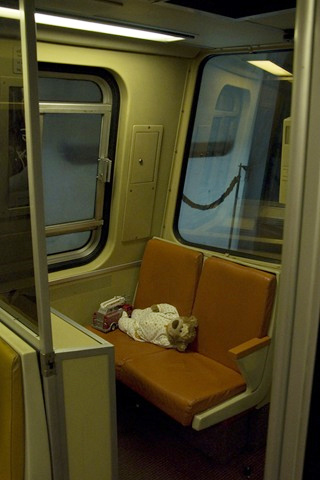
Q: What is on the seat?
A: A teddy bear.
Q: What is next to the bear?
A: A fire engine.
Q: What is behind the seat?
A: A window.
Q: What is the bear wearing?
A: Pajamas.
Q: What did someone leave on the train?
A: Toys.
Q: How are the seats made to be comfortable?
A: With cushions.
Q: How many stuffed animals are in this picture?
A: One.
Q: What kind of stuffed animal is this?
A: Teddy Bear.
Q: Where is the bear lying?
A: On the seat.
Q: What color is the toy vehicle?
A: Red.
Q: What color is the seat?
A: Brown.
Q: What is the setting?
A: A train.